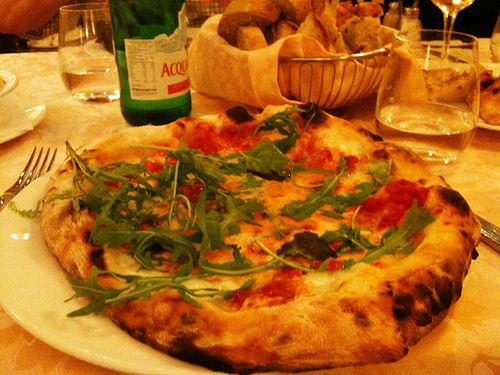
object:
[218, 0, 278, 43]
bread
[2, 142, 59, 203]
fork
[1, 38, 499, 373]
table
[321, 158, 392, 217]
basil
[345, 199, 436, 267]
basil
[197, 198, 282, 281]
basil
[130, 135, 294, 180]
basil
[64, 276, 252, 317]
basil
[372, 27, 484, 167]
cup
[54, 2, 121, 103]
cup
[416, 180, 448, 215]
ground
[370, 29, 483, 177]
glass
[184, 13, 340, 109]
cloth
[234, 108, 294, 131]
lettuce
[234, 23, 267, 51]
bread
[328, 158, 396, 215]
green lettuce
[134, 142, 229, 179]
green lettuce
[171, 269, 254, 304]
green lettuce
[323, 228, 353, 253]
green lettuce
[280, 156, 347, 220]
basil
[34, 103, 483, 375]
food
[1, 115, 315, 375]
dinner plate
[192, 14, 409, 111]
basket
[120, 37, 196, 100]
label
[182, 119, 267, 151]
red sauce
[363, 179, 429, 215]
red sauce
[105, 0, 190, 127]
bottle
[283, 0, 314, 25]
sliced bread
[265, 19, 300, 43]
bread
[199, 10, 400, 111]
bowl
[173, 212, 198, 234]
basil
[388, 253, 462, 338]
spot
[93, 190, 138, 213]
lettuce